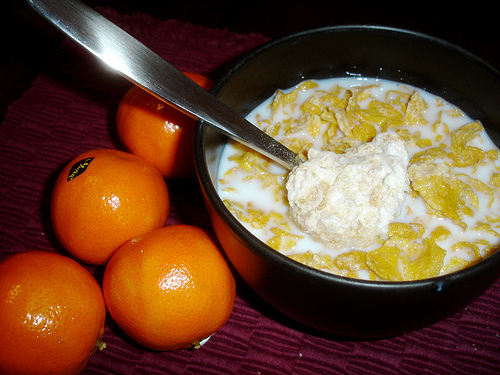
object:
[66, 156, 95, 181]
sticker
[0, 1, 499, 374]
mat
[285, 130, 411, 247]
sugar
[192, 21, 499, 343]
bowl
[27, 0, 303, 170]
spoon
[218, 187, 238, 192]
corn flakes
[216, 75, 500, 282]
milk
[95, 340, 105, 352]
stem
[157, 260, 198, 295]
light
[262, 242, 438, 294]
light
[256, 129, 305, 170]
powder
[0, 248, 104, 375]
fruit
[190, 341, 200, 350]
stem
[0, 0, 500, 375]
table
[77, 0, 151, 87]
reflection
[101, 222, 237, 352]
peel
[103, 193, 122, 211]
light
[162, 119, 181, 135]
light